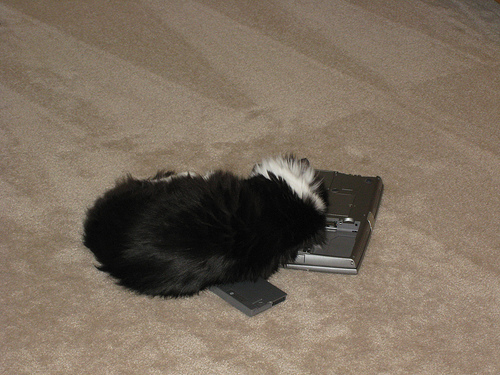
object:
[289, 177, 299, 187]
white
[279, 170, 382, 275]
laptop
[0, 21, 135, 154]
marks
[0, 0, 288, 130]
marks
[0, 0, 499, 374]
carpet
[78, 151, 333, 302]
animal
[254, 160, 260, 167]
nose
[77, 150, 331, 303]
dog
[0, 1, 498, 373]
room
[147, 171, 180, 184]
leg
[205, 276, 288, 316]
pack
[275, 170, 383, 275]
battery pack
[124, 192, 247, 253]
fur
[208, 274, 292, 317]
cell phone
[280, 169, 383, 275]
device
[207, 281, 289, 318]
battery